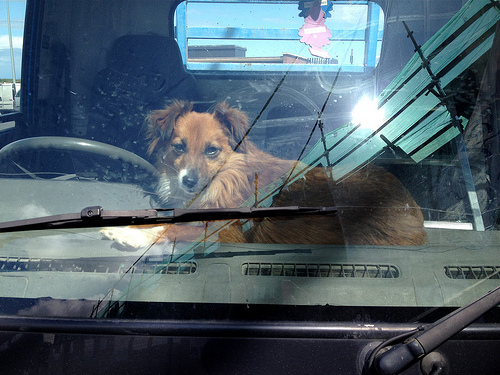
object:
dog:
[98, 100, 428, 252]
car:
[0, 1, 496, 372]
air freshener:
[295, 7, 335, 60]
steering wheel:
[0, 136, 163, 185]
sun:
[343, 88, 388, 136]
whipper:
[0, 202, 342, 236]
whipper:
[363, 283, 499, 375]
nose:
[181, 168, 199, 189]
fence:
[305, 57, 339, 64]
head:
[141, 100, 250, 196]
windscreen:
[1, 2, 495, 322]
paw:
[99, 224, 161, 252]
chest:
[156, 170, 226, 213]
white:
[177, 167, 186, 192]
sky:
[0, 0, 383, 80]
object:
[186, 43, 309, 63]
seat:
[82, 32, 200, 183]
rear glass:
[171, 1, 386, 73]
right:
[3, 141, 340, 311]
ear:
[211, 98, 251, 155]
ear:
[142, 97, 192, 156]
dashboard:
[1, 175, 499, 304]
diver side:
[26, 37, 197, 176]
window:
[0, 3, 38, 119]